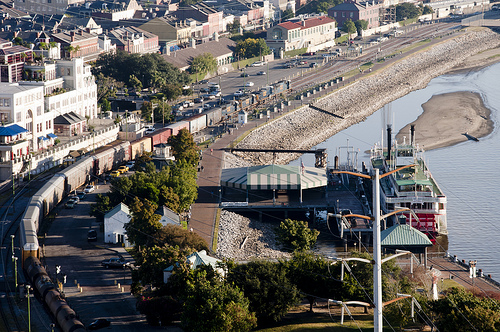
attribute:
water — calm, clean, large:
[446, 143, 500, 226]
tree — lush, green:
[289, 252, 329, 315]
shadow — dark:
[298, 311, 353, 321]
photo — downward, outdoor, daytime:
[0, 1, 495, 327]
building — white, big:
[6, 73, 101, 132]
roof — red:
[274, 7, 337, 34]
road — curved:
[48, 178, 104, 313]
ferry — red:
[374, 126, 449, 236]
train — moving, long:
[209, 81, 287, 126]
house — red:
[269, 22, 341, 51]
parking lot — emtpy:
[113, 275, 132, 286]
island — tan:
[388, 84, 492, 156]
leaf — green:
[183, 178, 190, 184]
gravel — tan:
[271, 109, 316, 150]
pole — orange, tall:
[336, 165, 417, 331]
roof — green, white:
[220, 165, 334, 190]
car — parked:
[102, 259, 128, 269]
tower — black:
[24, 284, 32, 300]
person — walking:
[209, 148, 216, 158]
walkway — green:
[193, 155, 219, 236]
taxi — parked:
[118, 164, 128, 174]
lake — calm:
[445, 153, 497, 261]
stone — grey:
[367, 61, 424, 102]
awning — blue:
[2, 123, 24, 138]